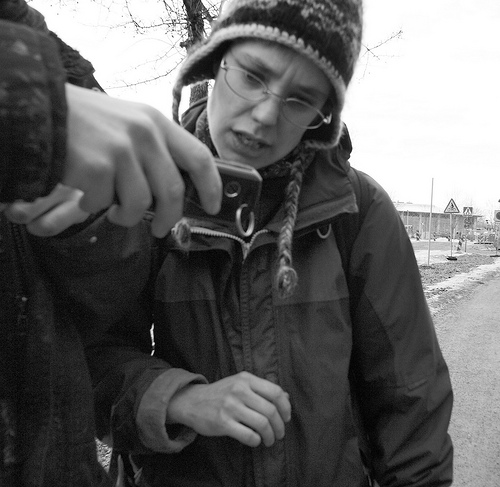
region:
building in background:
[403, 205, 489, 247]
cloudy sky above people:
[78, 0, 450, 143]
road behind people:
[437, 265, 492, 475]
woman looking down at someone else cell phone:
[0, 2, 436, 464]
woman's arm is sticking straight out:
[88, 327, 298, 440]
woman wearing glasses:
[207, 52, 320, 135]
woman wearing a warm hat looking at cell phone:
[162, 1, 412, 467]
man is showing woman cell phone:
[48, 0, 358, 246]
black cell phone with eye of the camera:
[170, 155, 266, 227]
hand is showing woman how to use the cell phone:
[5, 1, 386, 433]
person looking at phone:
[191, 150, 266, 227]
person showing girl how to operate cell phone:
[6, 0, 428, 432]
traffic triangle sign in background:
[446, 191, 460, 266]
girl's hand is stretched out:
[76, 321, 346, 467]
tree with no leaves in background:
[116, 0, 220, 47]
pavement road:
[447, 272, 498, 452]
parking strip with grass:
[422, 247, 495, 311]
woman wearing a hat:
[3, 0, 396, 216]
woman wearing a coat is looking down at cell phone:
[12, 27, 463, 483]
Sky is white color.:
[398, 44, 493, 183]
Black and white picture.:
[30, 21, 465, 421]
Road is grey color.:
[455, 310, 495, 390]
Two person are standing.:
[30, 65, 321, 407]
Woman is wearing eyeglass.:
[220, 51, 330, 137]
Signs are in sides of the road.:
[431, 185, 476, 265]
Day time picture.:
[35, 15, 465, 460]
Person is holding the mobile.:
[96, 100, 262, 230]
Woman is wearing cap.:
[227, 11, 372, 81]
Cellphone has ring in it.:
[211, 167, 261, 246]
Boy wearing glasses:
[216, 55, 333, 138]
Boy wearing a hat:
[217, 0, 377, 80]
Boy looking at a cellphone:
[193, 32, 341, 249]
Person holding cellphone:
[90, 82, 322, 238]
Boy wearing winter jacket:
[153, 202, 405, 477]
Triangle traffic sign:
[440, 188, 463, 266]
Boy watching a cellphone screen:
[161, 21, 337, 231]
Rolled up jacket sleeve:
[133, 373, 195, 458]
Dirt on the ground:
[432, 250, 487, 301]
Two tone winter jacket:
[153, 245, 402, 413]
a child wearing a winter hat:
[190, 19, 417, 366]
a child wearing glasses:
[176, 20, 362, 282]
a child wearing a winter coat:
[175, 42, 414, 464]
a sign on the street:
[442, 193, 460, 263]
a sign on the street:
[458, 195, 493, 260]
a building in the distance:
[407, 188, 457, 247]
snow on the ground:
[437, 262, 488, 297]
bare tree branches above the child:
[144, 1, 204, 44]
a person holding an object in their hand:
[8, 19, 263, 251]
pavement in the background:
[458, 307, 496, 414]